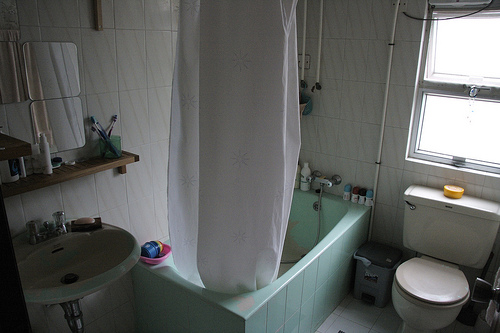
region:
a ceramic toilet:
[390, 176, 498, 331]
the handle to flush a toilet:
[401, 197, 419, 216]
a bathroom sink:
[1, 201, 143, 331]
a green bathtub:
[126, 162, 384, 330]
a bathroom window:
[407, 2, 499, 180]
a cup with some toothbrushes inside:
[83, 106, 129, 167]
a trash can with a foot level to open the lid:
[348, 239, 408, 312]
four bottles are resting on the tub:
[338, 181, 380, 213]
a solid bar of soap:
[71, 212, 103, 226]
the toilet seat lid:
[393, 247, 469, 309]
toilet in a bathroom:
[385, 177, 492, 329]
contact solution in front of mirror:
[35, 130, 56, 175]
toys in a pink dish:
[137, 232, 171, 268]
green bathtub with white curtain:
[130, 185, 380, 322]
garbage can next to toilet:
[346, 235, 403, 315]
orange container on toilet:
[439, 174, 469, 204]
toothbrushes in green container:
[80, 106, 125, 164]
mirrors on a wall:
[2, 31, 90, 161]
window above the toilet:
[400, 68, 498, 187]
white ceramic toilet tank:
[400, 186, 499, 273]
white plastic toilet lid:
[396, 256, 467, 301]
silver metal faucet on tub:
[304, 172, 334, 188]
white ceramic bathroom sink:
[16, 219, 141, 304]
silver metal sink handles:
[51, 209, 69, 234]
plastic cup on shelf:
[98, 134, 122, 160]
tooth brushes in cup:
[87, 113, 119, 136]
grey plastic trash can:
[352, 242, 399, 309]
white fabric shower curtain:
[166, 2, 302, 293]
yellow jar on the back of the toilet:
[441, 185, 466, 197]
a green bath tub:
[136, 185, 369, 328]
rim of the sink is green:
[30, 236, 137, 301]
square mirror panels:
[0, 39, 87, 153]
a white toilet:
[394, 183, 496, 332]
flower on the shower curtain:
[230, 225, 248, 248]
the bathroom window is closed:
[413, 5, 499, 180]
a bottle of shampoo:
[300, 162, 312, 192]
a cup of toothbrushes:
[85, 113, 121, 161]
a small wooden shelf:
[9, 151, 136, 195]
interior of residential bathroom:
[3, 4, 496, 327]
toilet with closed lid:
[389, 184, 498, 331]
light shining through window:
[414, 10, 498, 175]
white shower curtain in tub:
[163, 0, 302, 300]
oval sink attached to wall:
[14, 194, 139, 306]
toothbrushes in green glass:
[87, 111, 123, 157]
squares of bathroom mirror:
[1, 39, 88, 151]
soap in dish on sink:
[69, 214, 103, 231]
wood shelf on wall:
[0, 150, 140, 200]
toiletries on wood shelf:
[0, 133, 59, 181]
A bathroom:
[10, 8, 497, 331]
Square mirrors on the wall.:
[2, 36, 97, 156]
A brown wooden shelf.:
[11, 148, 141, 210]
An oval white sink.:
[9, 216, 143, 303]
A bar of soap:
[73, 215, 95, 227]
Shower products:
[292, 165, 378, 205]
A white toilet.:
[389, 175, 496, 331]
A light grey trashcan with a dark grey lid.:
[348, 237, 398, 314]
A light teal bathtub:
[134, 178, 365, 330]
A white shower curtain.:
[165, 0, 290, 291]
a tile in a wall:
[264, 290, 290, 327]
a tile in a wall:
[281, 277, 302, 305]